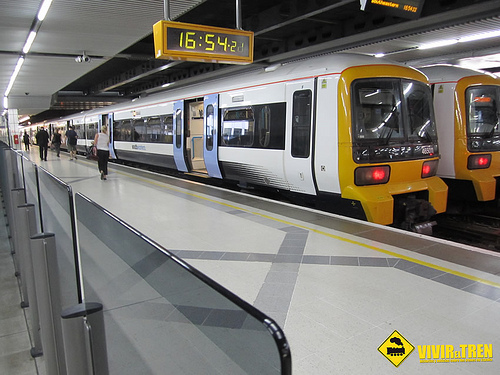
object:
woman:
[93, 124, 110, 179]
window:
[351, 76, 441, 164]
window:
[110, 110, 176, 148]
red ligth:
[371, 167, 386, 181]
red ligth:
[422, 164, 431, 176]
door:
[201, 93, 224, 180]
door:
[172, 99, 191, 173]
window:
[206, 103, 212, 153]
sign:
[152, 19, 258, 64]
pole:
[161, 0, 173, 18]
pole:
[235, 0, 242, 28]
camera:
[74, 54, 91, 64]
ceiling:
[0, 0, 498, 123]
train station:
[0, 0, 500, 375]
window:
[175, 108, 181, 149]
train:
[22, 51, 451, 236]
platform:
[0, 128, 497, 373]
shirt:
[96, 133, 110, 152]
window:
[218, 104, 255, 148]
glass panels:
[1, 142, 296, 375]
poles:
[27, 232, 65, 375]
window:
[462, 81, 500, 154]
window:
[87, 122, 98, 139]